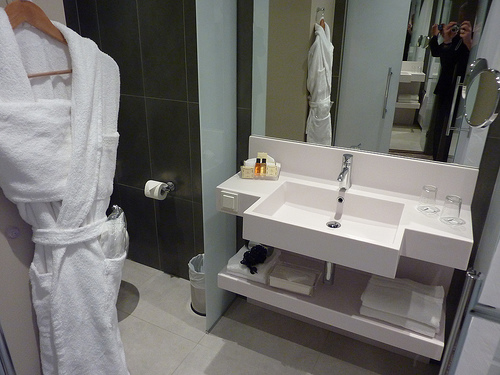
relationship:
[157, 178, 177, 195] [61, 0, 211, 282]
dispenser attached to wall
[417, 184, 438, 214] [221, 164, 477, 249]
glass sitting on counter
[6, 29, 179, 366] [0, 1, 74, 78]
robe hanging on hanger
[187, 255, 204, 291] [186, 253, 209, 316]
liner in trash bin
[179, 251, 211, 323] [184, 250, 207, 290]
trash bin with plastic liner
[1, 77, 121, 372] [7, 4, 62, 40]
robe on hanger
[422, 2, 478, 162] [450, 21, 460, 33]
man holding camera